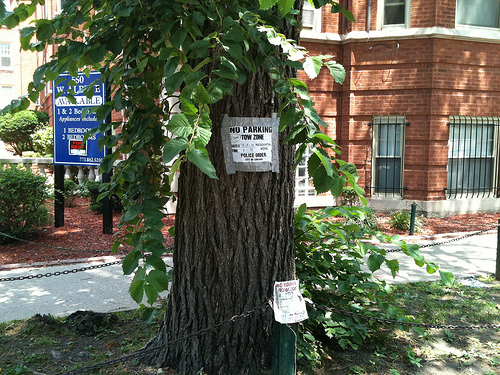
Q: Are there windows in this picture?
A: Yes, there are windows.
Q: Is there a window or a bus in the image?
A: Yes, there are windows.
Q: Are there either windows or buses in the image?
A: Yes, there are windows.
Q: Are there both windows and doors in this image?
A: No, there are windows but no doors.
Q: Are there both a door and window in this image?
A: No, there are windows but no doors.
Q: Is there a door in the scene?
A: No, there are no doors.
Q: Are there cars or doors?
A: No, there are no doors or cars.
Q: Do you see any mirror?
A: No, there are no mirrors.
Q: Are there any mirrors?
A: No, there are no mirrors.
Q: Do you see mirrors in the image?
A: No, there are no mirrors.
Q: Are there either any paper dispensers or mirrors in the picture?
A: No, there are no mirrors or paper dispensers.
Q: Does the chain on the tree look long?
A: Yes, the chain is long.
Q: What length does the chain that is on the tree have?
A: The chain has long length.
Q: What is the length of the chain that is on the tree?
A: The chain is long.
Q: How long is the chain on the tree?
A: The chain is long.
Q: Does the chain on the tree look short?
A: No, the chain is long.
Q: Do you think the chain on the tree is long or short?
A: The chain is long.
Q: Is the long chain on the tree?
A: Yes, the chain is on the tree.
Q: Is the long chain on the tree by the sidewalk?
A: Yes, the chain is on the tree.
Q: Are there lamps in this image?
A: No, there are no lamps.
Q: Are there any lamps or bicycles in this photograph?
A: No, there are no lamps or bicycles.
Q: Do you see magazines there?
A: No, there are no magazines.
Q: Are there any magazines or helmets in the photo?
A: No, there are no magazines or helmets.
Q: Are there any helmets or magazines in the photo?
A: No, there are no magazines or helmets.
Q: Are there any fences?
A: Yes, there is a fence.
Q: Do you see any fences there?
A: Yes, there is a fence.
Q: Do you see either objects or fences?
A: Yes, there is a fence.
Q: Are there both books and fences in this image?
A: No, there is a fence but no books.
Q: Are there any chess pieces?
A: No, there are no chess pieces.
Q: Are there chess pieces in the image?
A: No, there are no chess pieces.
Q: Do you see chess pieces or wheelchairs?
A: No, there are no chess pieces or wheelchairs.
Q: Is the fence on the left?
A: Yes, the fence is on the left of the image.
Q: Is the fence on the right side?
A: No, the fence is on the left of the image.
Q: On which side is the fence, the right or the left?
A: The fence is on the left of the image.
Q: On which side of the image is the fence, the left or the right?
A: The fence is on the left of the image.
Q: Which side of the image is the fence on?
A: The fence is on the left of the image.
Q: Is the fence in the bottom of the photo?
A: Yes, the fence is in the bottom of the image.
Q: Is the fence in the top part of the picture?
A: No, the fence is in the bottom of the image.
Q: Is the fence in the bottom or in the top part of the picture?
A: The fence is in the bottom of the image.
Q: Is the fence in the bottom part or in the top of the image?
A: The fence is in the bottom of the image.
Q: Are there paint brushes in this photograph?
A: No, there are no paint brushes.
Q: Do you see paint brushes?
A: No, there are no paint brushes.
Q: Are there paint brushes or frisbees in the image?
A: No, there are no paint brushes or frisbees.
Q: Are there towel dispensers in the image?
A: No, there are no towel dispensers.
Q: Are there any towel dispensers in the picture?
A: No, there are no towel dispensers.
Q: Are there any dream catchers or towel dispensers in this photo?
A: No, there are no towel dispensers or dream catchers.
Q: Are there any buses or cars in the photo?
A: No, there are no cars or buses.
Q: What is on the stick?
A: The sign is on the stick.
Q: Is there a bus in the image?
A: No, there are no buses.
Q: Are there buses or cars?
A: No, there are no buses or cars.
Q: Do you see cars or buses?
A: No, there are no buses or cars.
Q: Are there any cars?
A: No, there are no cars.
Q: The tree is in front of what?
A: The tree is in front of the sidewalk.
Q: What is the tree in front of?
A: The tree is in front of the sidewalk.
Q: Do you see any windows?
A: Yes, there is a window.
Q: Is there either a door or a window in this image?
A: Yes, there is a window.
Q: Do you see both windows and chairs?
A: No, there is a window but no chairs.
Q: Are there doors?
A: No, there are no doors.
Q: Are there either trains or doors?
A: No, there are no doors or trains.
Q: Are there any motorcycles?
A: No, there are no motorcycles.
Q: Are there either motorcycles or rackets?
A: No, there are no motorcycles or rackets.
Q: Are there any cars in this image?
A: No, there are no cars.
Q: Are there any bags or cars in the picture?
A: No, there are no cars or bags.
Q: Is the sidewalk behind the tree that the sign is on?
A: Yes, the sidewalk is behind the tree.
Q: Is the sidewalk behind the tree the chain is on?
A: Yes, the sidewalk is behind the tree.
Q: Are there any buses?
A: No, there are no buses.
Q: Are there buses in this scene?
A: No, there are no buses.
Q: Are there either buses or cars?
A: No, there are no buses or cars.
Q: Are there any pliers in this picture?
A: No, there are no pliers.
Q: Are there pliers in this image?
A: No, there are no pliers.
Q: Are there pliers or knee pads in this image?
A: No, there are no pliers or knee pads.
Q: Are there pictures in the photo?
A: No, there are no pictures.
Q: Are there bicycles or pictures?
A: No, there are no pictures or bicycles.